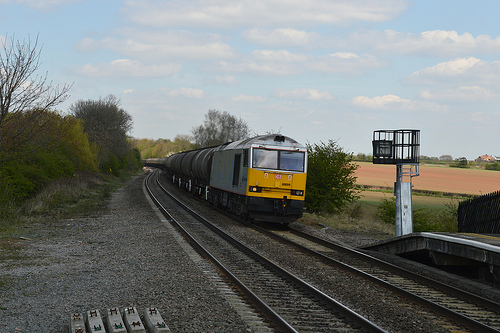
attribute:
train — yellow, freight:
[165, 134, 307, 222]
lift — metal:
[372, 129, 420, 234]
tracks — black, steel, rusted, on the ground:
[136, 156, 499, 332]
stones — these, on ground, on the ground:
[4, 167, 256, 328]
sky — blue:
[0, 1, 498, 161]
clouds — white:
[91, 0, 487, 111]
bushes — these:
[0, 108, 145, 207]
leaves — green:
[48, 144, 78, 159]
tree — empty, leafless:
[1, 39, 67, 162]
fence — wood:
[452, 189, 500, 230]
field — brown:
[345, 158, 499, 196]